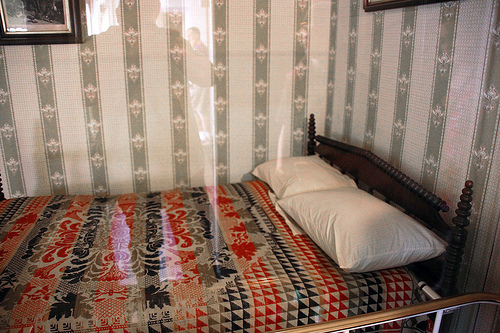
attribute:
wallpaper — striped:
[119, 40, 247, 158]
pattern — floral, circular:
[1, 190, 271, 331]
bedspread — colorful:
[0, 177, 430, 331]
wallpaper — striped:
[2, 3, 494, 180]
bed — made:
[4, 126, 474, 331]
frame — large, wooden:
[302, 110, 476, 286]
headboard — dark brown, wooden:
[275, 87, 487, 275]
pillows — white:
[248, 147, 453, 281]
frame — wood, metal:
[273, 288, 499, 331]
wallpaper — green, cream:
[109, 52, 257, 147]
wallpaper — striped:
[317, 0, 497, 325]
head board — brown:
[306, 113, 473, 332]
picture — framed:
[6, 2, 121, 67]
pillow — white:
[273, 184, 447, 273]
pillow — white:
[247, 152, 360, 199]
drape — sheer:
[0, 2, 498, 329]